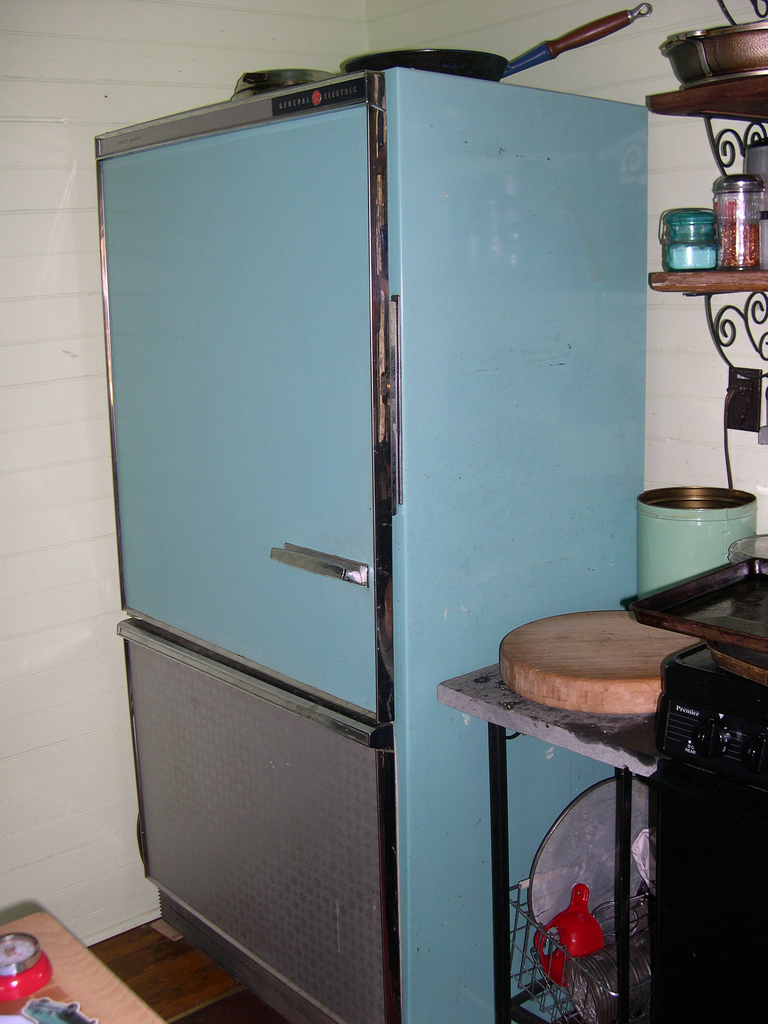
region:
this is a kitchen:
[30, 91, 615, 909]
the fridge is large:
[129, 124, 473, 617]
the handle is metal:
[258, 543, 411, 624]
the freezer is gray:
[138, 626, 377, 928]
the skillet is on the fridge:
[322, 32, 635, 108]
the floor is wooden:
[122, 931, 242, 1001]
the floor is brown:
[116, 923, 254, 1019]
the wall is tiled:
[37, 453, 148, 729]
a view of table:
[11, 890, 103, 1007]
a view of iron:
[499, 970, 571, 1002]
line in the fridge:
[322, 860, 469, 996]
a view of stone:
[132, 885, 215, 961]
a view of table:
[494, 570, 727, 752]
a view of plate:
[512, 801, 628, 948]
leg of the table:
[470, 840, 501, 923]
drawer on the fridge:
[329, 879, 372, 972]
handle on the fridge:
[267, 528, 365, 572]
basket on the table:
[513, 895, 563, 999]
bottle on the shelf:
[651, 194, 729, 269]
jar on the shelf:
[712, 179, 766, 270]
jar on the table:
[642, 499, 737, 590]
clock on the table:
[15, 928, 62, 996]